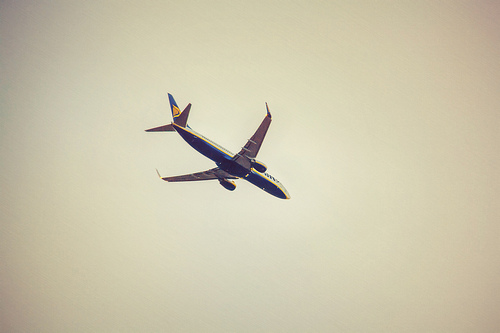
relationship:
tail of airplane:
[145, 92, 192, 135] [145, 93, 288, 199]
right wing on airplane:
[231, 98, 273, 174] [145, 93, 288, 199]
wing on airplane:
[158, 159, 238, 186] [145, 93, 288, 199]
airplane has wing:
[145, 93, 288, 199] [152, 163, 243, 182]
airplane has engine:
[145, 93, 288, 199] [214, 150, 256, 189]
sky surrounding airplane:
[0, 0, 498, 332] [145, 93, 288, 199]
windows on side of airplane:
[264, 170, 281, 182] [145, 93, 288, 199]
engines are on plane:
[221, 159, 268, 191] [143, 90, 289, 200]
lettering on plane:
[169, 101, 182, 116] [132, 90, 309, 219]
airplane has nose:
[145, 93, 288, 199] [277, 187, 289, 203]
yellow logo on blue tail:
[173, 108, 180, 117] [166, 90, 180, 119]